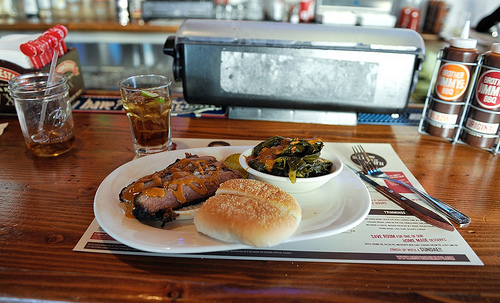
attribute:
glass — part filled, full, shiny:
[120, 72, 172, 153]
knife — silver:
[342, 159, 452, 231]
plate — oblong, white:
[93, 145, 373, 252]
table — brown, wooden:
[0, 109, 497, 302]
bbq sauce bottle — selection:
[414, 20, 482, 142]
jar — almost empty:
[9, 72, 77, 157]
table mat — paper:
[68, 137, 485, 273]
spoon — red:
[44, 34, 62, 61]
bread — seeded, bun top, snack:
[197, 175, 296, 242]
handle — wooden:
[378, 183, 451, 233]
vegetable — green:
[248, 132, 330, 180]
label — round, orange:
[437, 61, 470, 104]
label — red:
[473, 67, 499, 112]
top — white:
[448, 19, 475, 48]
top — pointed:
[490, 32, 498, 48]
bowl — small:
[236, 145, 348, 193]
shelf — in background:
[1, 12, 499, 51]